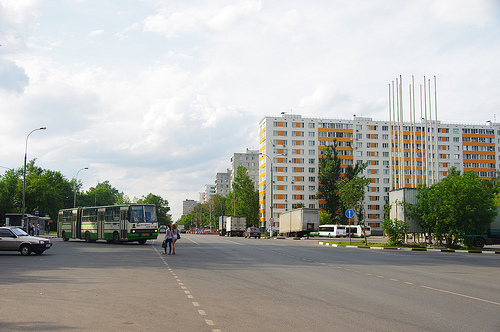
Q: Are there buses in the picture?
A: Yes, there are buses.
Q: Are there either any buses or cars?
A: Yes, there are buses.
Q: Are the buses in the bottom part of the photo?
A: Yes, the buses are in the bottom of the image.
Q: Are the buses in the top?
A: No, the buses are in the bottom of the image.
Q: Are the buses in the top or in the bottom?
A: The buses are in the bottom of the image.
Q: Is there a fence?
A: No, there are no fences.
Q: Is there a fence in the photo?
A: No, there are no fences.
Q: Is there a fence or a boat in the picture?
A: No, there are no fences or boats.